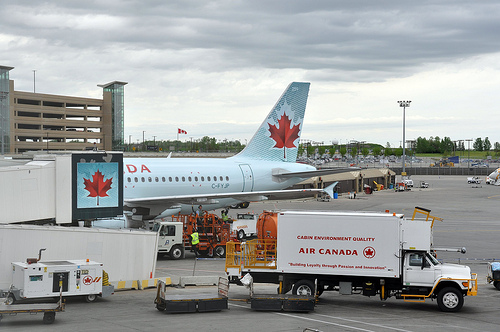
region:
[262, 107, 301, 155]
red maple leaf on plane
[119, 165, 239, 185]
windows on white airplane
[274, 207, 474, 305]
white box track with red lettering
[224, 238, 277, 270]
yellow railing behind white truck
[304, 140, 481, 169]
parking lot in background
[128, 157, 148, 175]
red lettering on white airplane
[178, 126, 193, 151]
canada flag in background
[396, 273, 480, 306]
yellow bars on white truck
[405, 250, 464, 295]
white cab of white truck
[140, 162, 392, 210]
wings of the airplane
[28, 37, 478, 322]
An airplane is at an airport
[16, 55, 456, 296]
Commercial aircraft is boarding passengers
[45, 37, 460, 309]
An airliner is preparing for takeoff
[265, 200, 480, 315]
A truck is delivering supplies to an airplane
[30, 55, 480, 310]
An airplane is parked at a terminal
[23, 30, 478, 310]
An aircraft is preparing for departure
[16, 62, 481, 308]
Commercial aircraft ready for passengers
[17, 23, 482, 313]
A cloudy day at an airport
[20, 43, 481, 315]
An airplane is being refueled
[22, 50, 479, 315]
An airport in a big city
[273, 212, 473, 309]
A white truck in the picture.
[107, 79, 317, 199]
A plane in the photo.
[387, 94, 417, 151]
A floodlight in the photo.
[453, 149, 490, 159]
Grass in the photo.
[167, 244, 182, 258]
A tyre in the photo.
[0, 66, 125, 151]
A building in the photo.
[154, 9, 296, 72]
A cloudy sky in the photo.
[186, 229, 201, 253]
A man in the photo.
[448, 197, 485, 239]
A surface with tarmac.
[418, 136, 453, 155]
Trees in the photo.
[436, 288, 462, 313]
A tyre in the photo.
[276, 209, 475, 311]
A truck in the photo.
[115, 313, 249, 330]
A surface with tarmac.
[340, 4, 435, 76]
Cloudy skies in the picture.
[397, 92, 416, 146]
Floodlights in the photo.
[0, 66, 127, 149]
A building in the background.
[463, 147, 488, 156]
Green grass in the picture.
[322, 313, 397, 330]
White markings in the photo.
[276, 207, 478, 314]
A white truck in the photo.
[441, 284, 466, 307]
A tyre in the photo.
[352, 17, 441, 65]
Cloudy skies in the photo.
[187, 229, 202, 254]
A person in the photo.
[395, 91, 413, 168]
A floodlight in the photo.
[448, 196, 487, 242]
A parking with tarmac.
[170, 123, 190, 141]
Flag in the photo.